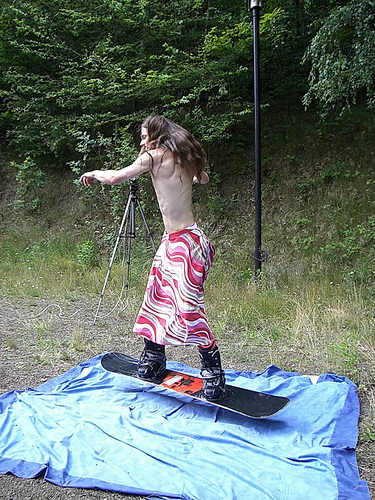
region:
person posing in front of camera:
[66, 108, 230, 403]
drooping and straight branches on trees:
[2, 4, 367, 181]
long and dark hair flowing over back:
[136, 105, 207, 195]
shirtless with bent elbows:
[75, 146, 210, 229]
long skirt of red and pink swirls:
[129, 218, 213, 342]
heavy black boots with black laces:
[130, 330, 220, 392]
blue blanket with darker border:
[0, 345, 369, 493]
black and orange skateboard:
[98, 346, 288, 417]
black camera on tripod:
[87, 174, 153, 325]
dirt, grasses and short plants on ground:
[6, 189, 367, 351]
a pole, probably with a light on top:
[236, 0, 271, 286]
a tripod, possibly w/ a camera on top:
[87, 168, 156, 330]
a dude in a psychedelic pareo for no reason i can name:
[125, 220, 218, 349]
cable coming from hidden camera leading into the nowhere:
[4, 201, 127, 331]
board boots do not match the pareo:
[133, 334, 231, 403]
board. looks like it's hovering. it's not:
[98, 346, 298, 423]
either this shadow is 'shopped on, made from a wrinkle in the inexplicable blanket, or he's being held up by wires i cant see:
[119, 386, 292, 444]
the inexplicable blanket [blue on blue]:
[0, 344, 373, 498]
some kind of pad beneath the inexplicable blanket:
[298, 371, 322, 385]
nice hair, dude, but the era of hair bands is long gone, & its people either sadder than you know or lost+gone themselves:
[65, 113, 231, 235]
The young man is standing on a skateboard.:
[76, 112, 288, 417]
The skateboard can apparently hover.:
[98, 349, 286, 413]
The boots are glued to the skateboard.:
[135, 335, 225, 397]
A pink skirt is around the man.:
[128, 218, 209, 340]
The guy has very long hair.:
[136, 111, 201, 178]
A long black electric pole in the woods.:
[247, 0, 258, 278]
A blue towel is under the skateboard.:
[0, 347, 368, 494]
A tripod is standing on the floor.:
[90, 173, 151, 323]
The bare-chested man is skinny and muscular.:
[75, 144, 204, 228]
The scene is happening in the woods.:
[0, 0, 371, 497]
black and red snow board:
[102, 351, 289, 423]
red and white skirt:
[138, 229, 216, 343]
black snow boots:
[137, 341, 225, 399]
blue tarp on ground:
[1, 351, 369, 499]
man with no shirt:
[73, 115, 234, 395]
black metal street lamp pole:
[251, 3, 264, 274]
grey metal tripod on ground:
[96, 187, 164, 315]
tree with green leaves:
[298, 3, 370, 125]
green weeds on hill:
[8, 160, 43, 222]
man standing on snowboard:
[80, 114, 229, 377]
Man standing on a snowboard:
[77, 113, 290, 422]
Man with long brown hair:
[136, 112, 208, 184]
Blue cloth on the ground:
[0, 348, 372, 498]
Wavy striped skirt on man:
[131, 225, 212, 348]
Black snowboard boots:
[133, 337, 263, 403]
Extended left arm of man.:
[79, 148, 177, 191]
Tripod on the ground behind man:
[95, 179, 155, 321]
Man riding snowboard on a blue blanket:
[1, 109, 366, 498]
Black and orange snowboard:
[96, 345, 290, 422]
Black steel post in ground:
[249, 0, 263, 283]